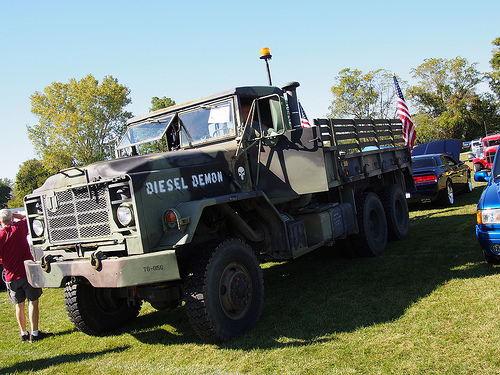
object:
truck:
[20, 85, 413, 346]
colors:
[135, 154, 189, 166]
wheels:
[353, 193, 389, 255]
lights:
[113, 203, 136, 227]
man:
[0, 207, 55, 343]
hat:
[1, 210, 13, 219]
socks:
[31, 328, 41, 336]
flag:
[390, 72, 419, 153]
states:
[390, 72, 418, 153]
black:
[432, 142, 440, 152]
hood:
[411, 138, 459, 161]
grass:
[0, 203, 499, 375]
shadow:
[213, 206, 482, 351]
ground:
[0, 195, 499, 211]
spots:
[370, 332, 392, 345]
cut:
[364, 324, 412, 365]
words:
[143, 170, 227, 198]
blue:
[4, 0, 93, 42]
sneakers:
[29, 330, 51, 340]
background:
[0, 0, 497, 374]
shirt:
[1, 219, 35, 282]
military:
[163, 149, 209, 167]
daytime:
[0, 0, 498, 374]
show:
[402, 122, 499, 268]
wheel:
[179, 233, 270, 342]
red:
[481, 135, 495, 145]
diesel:
[394, 138, 472, 211]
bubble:
[257, 48, 272, 61]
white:
[468, 142, 475, 152]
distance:
[456, 136, 488, 154]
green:
[145, 205, 159, 232]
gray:
[221, 298, 232, 311]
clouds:
[147, 53, 215, 85]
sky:
[0, 0, 500, 187]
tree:
[27, 75, 127, 176]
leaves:
[110, 88, 120, 100]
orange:
[260, 46, 270, 55]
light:
[434, 317, 490, 359]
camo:
[195, 152, 235, 173]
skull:
[237, 165, 246, 182]